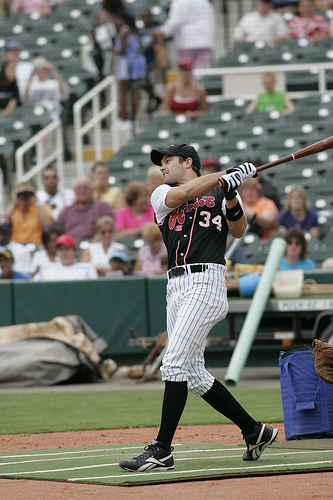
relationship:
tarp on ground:
[7, 312, 107, 392] [0, 367, 280, 411]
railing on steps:
[11, 75, 142, 197] [47, 98, 138, 195]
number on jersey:
[196, 205, 223, 233] [151, 185, 248, 270]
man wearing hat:
[118, 141, 279, 473] [142, 126, 207, 186]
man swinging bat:
[118, 141, 279, 473] [258, 130, 331, 173]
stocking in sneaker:
[199, 379, 259, 433] [241, 419, 279, 462]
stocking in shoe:
[152, 377, 190, 444] [119, 439, 176, 473]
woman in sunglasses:
[233, 225, 319, 298] [284, 237, 303, 247]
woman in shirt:
[233, 225, 319, 298] [236, 254, 322, 296]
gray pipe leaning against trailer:
[222, 234, 287, 389] [219, 296, 332, 345]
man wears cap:
[118, 142, 278, 473] [150, 143, 201, 170]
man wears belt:
[118, 142, 278, 473] [167, 263, 209, 278]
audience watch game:
[2, 5, 332, 259] [4, 129, 331, 491]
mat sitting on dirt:
[27, 439, 330, 481] [0, 419, 331, 497]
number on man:
[199, 210, 223, 232] [118, 142, 278, 473]